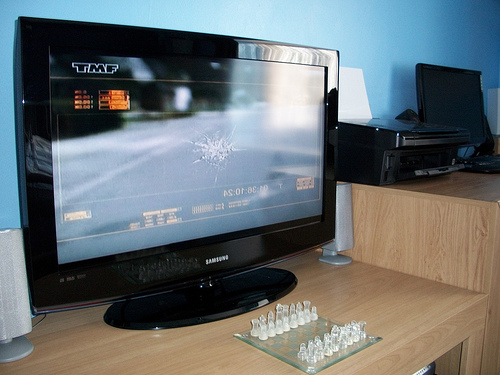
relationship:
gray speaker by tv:
[0, 228, 32, 364] [19, 18, 366, 330]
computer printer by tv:
[336, 119, 465, 181] [19, 18, 366, 330]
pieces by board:
[248, 297, 318, 339] [231, 315, 382, 373]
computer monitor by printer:
[16, 18, 337, 327] [345, 117, 467, 182]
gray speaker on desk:
[2, 225, 47, 363] [307, 182, 390, 259]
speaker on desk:
[316, 181, 356, 268] [0, 240, 491, 372]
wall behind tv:
[0, 0, 497, 255] [19, 18, 366, 330]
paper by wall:
[337, 67, 372, 119] [0, 0, 497, 255]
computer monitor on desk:
[413, 62, 486, 149] [333, 166, 498, 373]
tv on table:
[19, 17, 339, 331] [0, 287, 483, 374]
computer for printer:
[9, 16, 385, 359] [320, 107, 466, 189]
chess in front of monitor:
[212, 283, 349, 373] [51, 25, 346, 331]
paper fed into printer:
[336, 68, 375, 119] [335, 117, 480, 183]